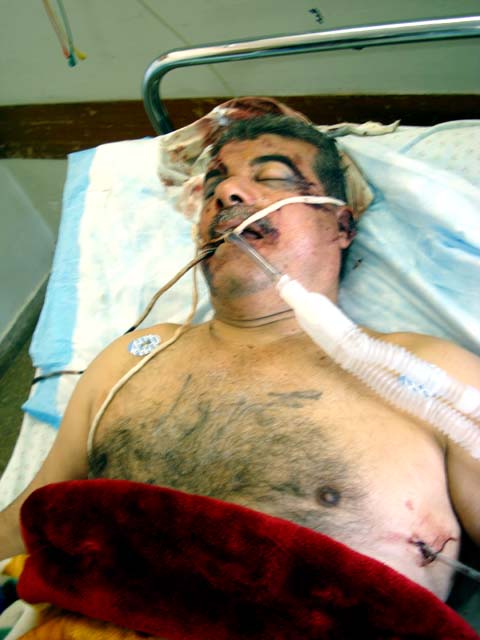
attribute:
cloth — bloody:
[152, 95, 401, 216]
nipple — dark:
[306, 484, 351, 520]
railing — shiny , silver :
[126, 17, 466, 91]